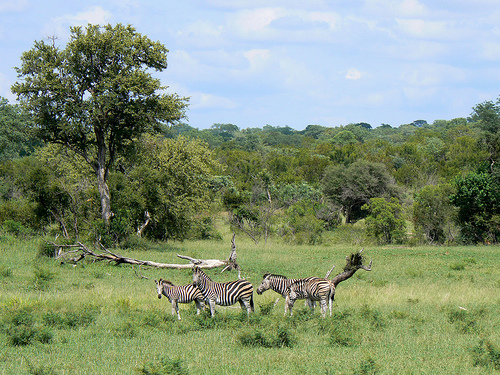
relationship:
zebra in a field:
[154, 276, 214, 319] [1, 235, 499, 372]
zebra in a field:
[188, 266, 256, 320] [1, 235, 499, 372]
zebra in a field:
[257, 270, 336, 322] [1, 235, 499, 372]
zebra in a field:
[287, 277, 336, 322] [1, 235, 499, 372]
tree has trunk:
[11, 23, 192, 245] [91, 125, 117, 231]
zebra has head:
[154, 276, 214, 319] [153, 278, 164, 300]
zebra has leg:
[188, 266, 256, 320] [206, 299, 217, 321]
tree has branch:
[53, 234, 245, 284] [96, 240, 121, 257]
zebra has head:
[188, 266, 256, 320] [189, 265, 202, 288]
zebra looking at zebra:
[257, 270, 336, 322] [188, 266, 256, 320]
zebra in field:
[257, 270, 336, 322] [1, 235, 499, 372]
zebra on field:
[257, 270, 336, 322] [1, 235, 499, 372]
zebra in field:
[154, 276, 214, 319] [1, 235, 499, 372]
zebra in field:
[188, 266, 256, 320] [1, 235, 499, 372]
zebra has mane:
[154, 276, 214, 319] [160, 279, 175, 286]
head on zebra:
[153, 278, 164, 300] [154, 276, 214, 319]